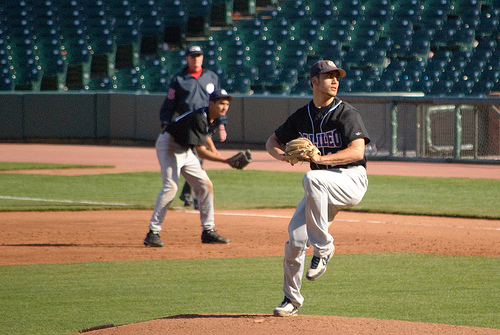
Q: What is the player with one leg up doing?
A: Pitching.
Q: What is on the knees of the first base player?
A: Dirt.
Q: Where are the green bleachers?
A: Behind the players.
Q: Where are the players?
A: On the baseball field.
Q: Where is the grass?
A: On the baseball field.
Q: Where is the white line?
A: On the field.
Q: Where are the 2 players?
A: Out in the field.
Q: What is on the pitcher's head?
A: A baseball hat.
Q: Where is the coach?
A: Standing on the field.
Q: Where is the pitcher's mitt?
A: On his left hand.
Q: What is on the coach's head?
A: A hat.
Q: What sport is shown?
A: Baseball.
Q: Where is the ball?
A: In the pitcher's hands.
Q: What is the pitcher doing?
A: Throwing the ball.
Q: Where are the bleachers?
A: Behind the players.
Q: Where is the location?
A: Baseball diamond.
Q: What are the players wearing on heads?
A: Hats.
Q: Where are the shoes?
A: On the player's feet.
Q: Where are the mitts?
A: On the player's hands.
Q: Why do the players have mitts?
A: To catch the ball.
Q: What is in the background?
A: Stadium seating.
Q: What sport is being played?
A: Baseball.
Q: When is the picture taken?
A: Daytime.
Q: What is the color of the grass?
A: Green.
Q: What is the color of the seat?
A: Blue.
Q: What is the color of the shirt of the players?
A: Black.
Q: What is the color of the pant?
A: Grey.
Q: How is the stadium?
A: Empty.